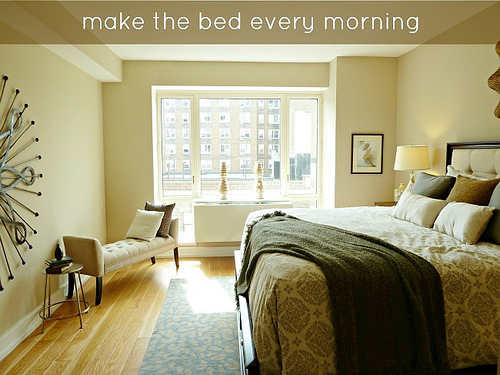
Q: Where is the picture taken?
A: A bedroom.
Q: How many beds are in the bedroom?
A: One.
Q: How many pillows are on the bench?
A: Two.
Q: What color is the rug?
A: Blue.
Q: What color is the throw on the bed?
A: Green.